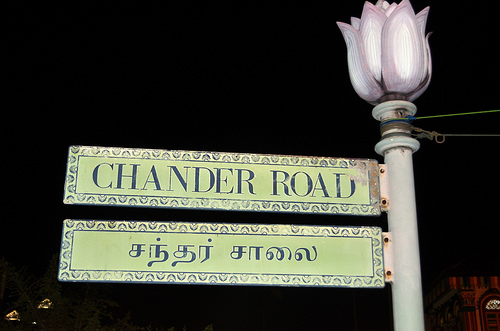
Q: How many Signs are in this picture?
A: 2.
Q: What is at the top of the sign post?
A: A flower.